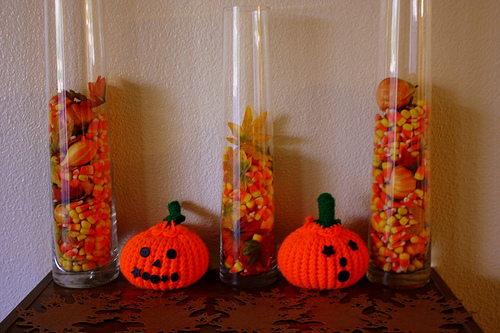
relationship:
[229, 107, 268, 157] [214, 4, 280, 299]
flower in bottle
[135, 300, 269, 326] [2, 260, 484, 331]
surface on table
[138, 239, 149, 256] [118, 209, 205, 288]
eye on pumpkin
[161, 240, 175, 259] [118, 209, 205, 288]
eye on pumpkin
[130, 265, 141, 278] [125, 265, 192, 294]
star in mouth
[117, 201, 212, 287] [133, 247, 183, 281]
pumpkin has face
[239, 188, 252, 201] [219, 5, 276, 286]
candy corn inside glass cylinder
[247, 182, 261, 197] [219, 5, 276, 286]
candy corn inside glass cylinder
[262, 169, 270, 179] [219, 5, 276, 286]
candy corn inside glass cylinder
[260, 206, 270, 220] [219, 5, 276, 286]
candy corn inside glass cylinder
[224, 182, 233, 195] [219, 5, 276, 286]
candy corn inside glass cylinder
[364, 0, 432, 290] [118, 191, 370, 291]
bottle on pumpkin counter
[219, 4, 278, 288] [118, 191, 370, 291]
bottle on pumpkin counter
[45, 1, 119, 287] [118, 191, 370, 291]
vase on pumpkin counter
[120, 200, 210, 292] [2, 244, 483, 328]
pumpkin on counter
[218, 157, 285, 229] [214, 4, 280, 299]
card corn in bottle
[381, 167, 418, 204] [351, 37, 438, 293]
pumpkin candy in bottle